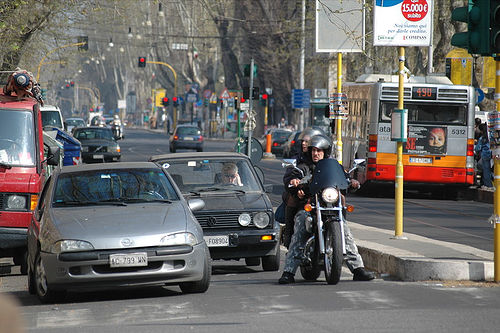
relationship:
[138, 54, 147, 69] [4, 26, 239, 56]
light suspended on wire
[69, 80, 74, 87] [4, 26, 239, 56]
traffic light suspended on wire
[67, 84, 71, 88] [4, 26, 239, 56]
traffic light suspended on wire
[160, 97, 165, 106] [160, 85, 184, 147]
light suspended on wire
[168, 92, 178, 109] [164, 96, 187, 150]
traffic light suspended on wire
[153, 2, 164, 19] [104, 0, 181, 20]
light suspended on wire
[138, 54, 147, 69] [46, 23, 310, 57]
light on wire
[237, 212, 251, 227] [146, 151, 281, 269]
headlight on car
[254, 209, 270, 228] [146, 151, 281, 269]
headlight on car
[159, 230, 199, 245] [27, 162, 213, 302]
headlight on car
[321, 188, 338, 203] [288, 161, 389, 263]
circle on motorcycle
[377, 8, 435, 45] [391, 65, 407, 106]
sign on pole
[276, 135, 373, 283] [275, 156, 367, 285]
man on motorcycle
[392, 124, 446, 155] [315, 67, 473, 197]
sign on bus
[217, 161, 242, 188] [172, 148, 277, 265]
person in car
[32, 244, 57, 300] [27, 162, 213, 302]
tire on car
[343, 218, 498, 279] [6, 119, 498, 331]
cement median in roadway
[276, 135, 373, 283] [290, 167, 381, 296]
man on motorcycle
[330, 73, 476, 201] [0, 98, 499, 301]
bus in lane of traffic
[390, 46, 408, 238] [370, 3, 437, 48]
yellow pole holds sign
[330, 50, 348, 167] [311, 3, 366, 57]
yellow pole holds sign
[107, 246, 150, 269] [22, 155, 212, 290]
license plate on car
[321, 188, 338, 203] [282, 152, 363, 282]
circle on motorcycle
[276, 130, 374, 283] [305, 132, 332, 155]
man wears helmet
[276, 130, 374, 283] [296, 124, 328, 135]
man wears helmet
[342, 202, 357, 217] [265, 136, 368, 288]
light on motorcycle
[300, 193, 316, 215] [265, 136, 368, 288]
light on motorcycle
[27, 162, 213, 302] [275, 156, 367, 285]
car next to motorcycle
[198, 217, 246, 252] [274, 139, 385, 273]
plate next to motorcycle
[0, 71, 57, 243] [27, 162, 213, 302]
truck behind car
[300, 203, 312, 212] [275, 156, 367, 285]
light on motorcycle